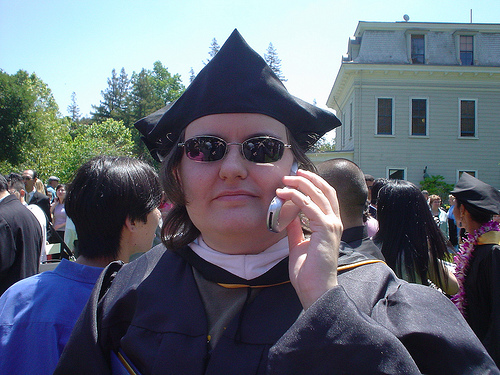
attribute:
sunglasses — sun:
[175, 140, 301, 164]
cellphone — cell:
[268, 162, 317, 236]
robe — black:
[126, 211, 493, 343]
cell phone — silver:
[253, 175, 308, 238]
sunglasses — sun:
[168, 120, 308, 186]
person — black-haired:
[18, 112, 203, 351]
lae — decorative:
[449, 225, 497, 304]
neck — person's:
[460, 221, 497, 242]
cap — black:
[130, 23, 342, 140]